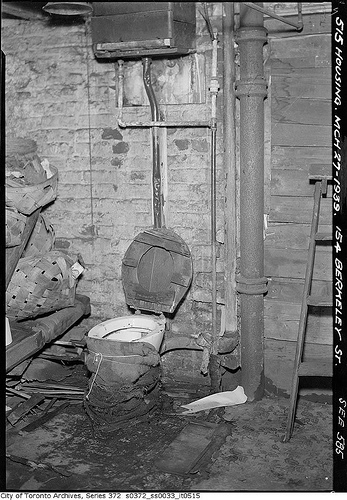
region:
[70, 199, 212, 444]
broken toilet in the room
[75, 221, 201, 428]
broken toilet in the room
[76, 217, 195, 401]
broken toilet in the room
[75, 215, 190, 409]
broken toilet in the room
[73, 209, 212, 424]
broken toilet in the room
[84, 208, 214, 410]
broken toilet in the room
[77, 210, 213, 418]
broken toilet in the room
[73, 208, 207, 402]
broken toilet in the room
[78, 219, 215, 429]
broken toilet in the room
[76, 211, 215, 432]
broken toilet in the room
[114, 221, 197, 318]
broken toilet lid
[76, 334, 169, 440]
burlap wrapped around base of toilet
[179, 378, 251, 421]
white paper on floor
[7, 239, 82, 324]
weaved basket against wall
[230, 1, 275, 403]
metal pipe along wall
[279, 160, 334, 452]
wooden ladder against wall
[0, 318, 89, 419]
pile of wood on floor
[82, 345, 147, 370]
piece of cord around burlap bag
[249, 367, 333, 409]
stain on wall and pipe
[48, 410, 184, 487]
stains on floor in front of toilet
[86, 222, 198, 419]
toilet against the wall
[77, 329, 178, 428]
bottom of toilet wrapped in cloth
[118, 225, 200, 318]
wooden toilet seat is broken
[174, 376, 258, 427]
piece of trash on the ground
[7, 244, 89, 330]
broken wooden basket in stack of trash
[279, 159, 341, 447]
ladder leaning against the wall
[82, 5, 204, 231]
box leading to pipe connected to toilet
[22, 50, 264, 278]
brick wall behind the toilet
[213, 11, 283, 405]
long, thick dark-colored pipe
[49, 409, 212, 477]
dirt on ground in front of toilet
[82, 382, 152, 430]
bottom of the toilet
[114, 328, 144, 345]
bowl of the toilet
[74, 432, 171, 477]
the ground is dirty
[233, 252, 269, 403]
pipe on the wall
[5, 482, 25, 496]
watermark for the photographer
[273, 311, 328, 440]
ladder on the right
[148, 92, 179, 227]
pipe on the wall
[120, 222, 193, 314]
wooden toilet seat against the wall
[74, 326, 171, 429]
cloth in front of a toilet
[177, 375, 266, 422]
white paper on the floor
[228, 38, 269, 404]
drain pipe running up the wall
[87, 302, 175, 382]
white toilet bowl on the floor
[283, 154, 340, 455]
ladder leaning against the wall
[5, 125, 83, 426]
Pile of debris on the floor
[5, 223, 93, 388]
Pile of debris on the floor